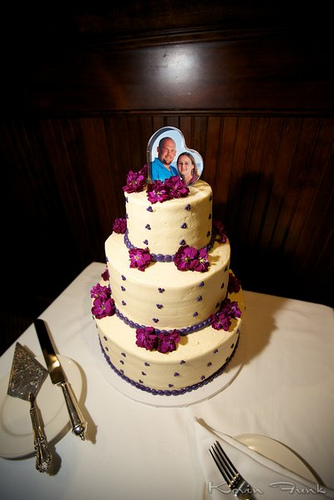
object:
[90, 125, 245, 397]
cake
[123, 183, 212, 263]
tiers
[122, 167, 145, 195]
flowers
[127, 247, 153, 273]
flowers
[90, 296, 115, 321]
flowers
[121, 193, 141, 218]
trim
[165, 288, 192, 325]
trim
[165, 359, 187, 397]
trim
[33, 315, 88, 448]
cake knife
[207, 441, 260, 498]
fork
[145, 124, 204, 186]
heart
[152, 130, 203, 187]
photo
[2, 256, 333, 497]
table cloth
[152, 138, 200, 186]
couple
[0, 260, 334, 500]
table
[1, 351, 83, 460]
dish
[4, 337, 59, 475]
spatula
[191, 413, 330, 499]
napkin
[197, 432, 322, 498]
dish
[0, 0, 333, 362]
wall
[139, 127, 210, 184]
frame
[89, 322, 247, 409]
plate